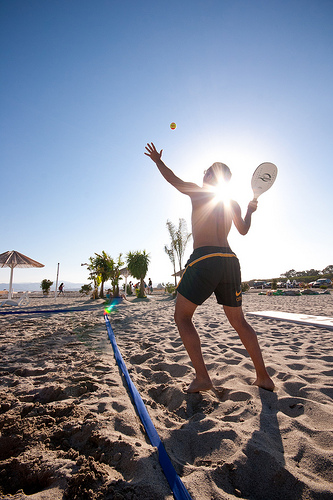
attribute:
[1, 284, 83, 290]
water — blue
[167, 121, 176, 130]
ball — round, yellow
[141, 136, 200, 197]
arm — outstretched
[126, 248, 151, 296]
tree — green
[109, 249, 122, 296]
tree — green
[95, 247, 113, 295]
tree — green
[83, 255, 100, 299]
tree — green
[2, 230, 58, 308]
umbrella — straw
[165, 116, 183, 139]
ball — yellow, round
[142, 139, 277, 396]
man — shirtless, caucation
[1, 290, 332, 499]
sand — brown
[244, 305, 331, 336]
rectangle — white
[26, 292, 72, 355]
beach — sand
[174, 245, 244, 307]
shorts — black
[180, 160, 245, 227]
sun rays — bright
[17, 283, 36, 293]
mountain — hazy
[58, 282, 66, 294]
person — walking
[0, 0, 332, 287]
sky — blue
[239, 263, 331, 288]
trees — green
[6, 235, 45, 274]
umbrella — open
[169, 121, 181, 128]
ball — round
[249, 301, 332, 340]
board — white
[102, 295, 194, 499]
rope — blue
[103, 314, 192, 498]
line — blue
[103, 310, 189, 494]
ribbon — blue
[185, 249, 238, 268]
stripes — yellow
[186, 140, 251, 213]
sun — bright